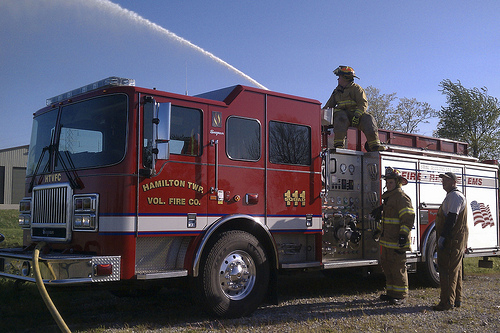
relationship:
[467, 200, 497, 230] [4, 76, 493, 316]
flag on firetruck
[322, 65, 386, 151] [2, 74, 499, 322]
firefighter on truck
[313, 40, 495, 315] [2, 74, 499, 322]
firefighters beside truck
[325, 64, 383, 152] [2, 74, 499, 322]
firefighter seated on top of truck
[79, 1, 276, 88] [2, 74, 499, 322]
water coming out of truck